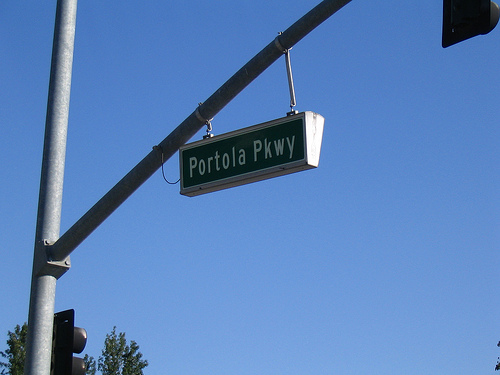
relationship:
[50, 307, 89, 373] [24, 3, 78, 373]
light on pole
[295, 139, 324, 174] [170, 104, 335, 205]
corner of sign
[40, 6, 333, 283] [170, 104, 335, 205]
pole next to sign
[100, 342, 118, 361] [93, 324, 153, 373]
leaves on tree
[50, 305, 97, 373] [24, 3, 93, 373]
light on pole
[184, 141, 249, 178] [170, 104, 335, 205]
words on sign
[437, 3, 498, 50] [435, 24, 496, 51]
traffic light has bottom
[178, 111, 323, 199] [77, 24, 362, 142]
sign on pole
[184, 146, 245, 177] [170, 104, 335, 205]
words on sign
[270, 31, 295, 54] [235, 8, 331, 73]
clamps on pole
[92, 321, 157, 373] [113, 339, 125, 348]
tree top has leaves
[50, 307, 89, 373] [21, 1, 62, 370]
light on pole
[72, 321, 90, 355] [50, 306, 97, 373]
covers on street lights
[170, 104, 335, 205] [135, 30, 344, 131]
sign on pole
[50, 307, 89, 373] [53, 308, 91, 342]
light has top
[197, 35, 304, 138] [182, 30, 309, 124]
clamps on pole